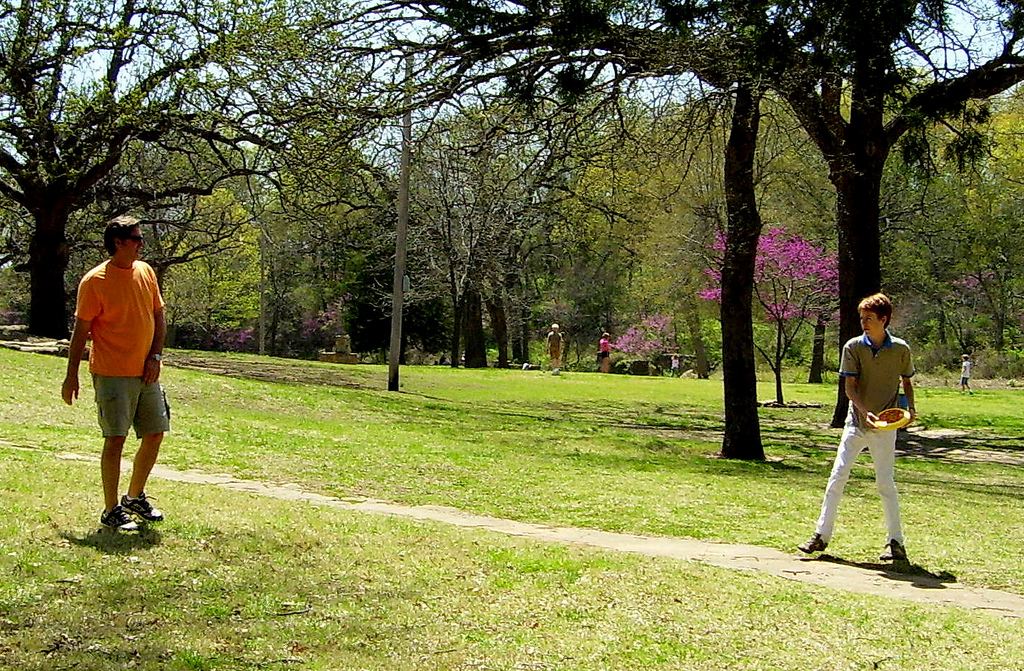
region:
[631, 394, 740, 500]
A person eating a orange.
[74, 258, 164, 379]
Man in an orange shirt is standing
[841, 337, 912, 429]
Man in a grey shirt is standing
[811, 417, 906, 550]
Boy is wearing white pants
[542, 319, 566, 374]
A person is walking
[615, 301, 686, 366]
Pink tree is growing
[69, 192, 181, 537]
man playing frisbee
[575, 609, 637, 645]
short green and yellow grass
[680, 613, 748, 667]
short green and yellow grass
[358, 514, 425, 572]
short green and yellow grass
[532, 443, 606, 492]
short green and yellow grass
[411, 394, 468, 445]
short green and yellow grass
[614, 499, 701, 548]
short green and yellow grass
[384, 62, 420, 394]
a tall gray pole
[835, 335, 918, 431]
a boy's short sleeve shirt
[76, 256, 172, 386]
a man's orange shirt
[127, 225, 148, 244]
dark black sunglasses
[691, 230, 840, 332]
purple tree leaves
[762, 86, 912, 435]
a large tree trunk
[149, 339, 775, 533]
a section of green grass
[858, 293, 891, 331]
short cut brown hair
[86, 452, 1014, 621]
a long dirt trail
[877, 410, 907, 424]
A hand preparing to throw a frisbee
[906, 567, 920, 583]
The shadow of the person on the ground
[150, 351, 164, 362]
A watch strapped around the wrist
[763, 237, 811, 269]
Purple flowers between two trees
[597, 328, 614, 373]
A person standing next to a flowery bush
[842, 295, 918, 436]
A person about to throw a frisbee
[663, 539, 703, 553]
A bare path between the grass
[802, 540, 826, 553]
A foot raised above the ground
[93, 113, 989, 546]
people playing at the park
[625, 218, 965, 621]
boy holding a Frisbee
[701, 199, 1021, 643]
a red and yellow Frisbee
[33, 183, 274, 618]
man wearing sunglasses's at the park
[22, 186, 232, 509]
man wearing an orange shirt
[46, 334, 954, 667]
a walk way in the park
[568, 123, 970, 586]
purple flowers on the tree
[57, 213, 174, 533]
Brown haired man in an orange shirt.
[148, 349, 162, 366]
Watch on a mans left wrist.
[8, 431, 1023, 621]
Narrow path coming down between the grass.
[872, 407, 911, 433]
Yellow and red frisbee.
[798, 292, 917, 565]
Brown haired man in a green and blue shirt.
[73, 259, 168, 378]
Orange t-shirt on a man.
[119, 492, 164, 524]
A mans left black and white tennis shoe.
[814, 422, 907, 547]
White pair of pants on a man.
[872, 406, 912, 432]
Yellow frisbee with red center.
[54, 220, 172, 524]
a person is playing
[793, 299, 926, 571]
a person is standing up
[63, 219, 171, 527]
a person is standing up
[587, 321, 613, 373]
a person is standing up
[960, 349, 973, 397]
a person is standing up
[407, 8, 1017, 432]
a tree in a field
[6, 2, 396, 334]
a tree in a field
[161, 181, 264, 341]
a tree in a field